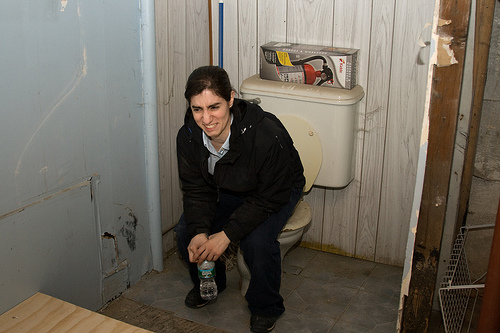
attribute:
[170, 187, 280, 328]
jeans — blue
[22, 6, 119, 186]
wall — wooden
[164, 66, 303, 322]
woman — sitting, seated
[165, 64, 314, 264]
woman — making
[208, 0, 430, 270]
panels — Wood 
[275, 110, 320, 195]
lid — lifted, open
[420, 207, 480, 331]
tray — wire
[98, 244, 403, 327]
floor — cement